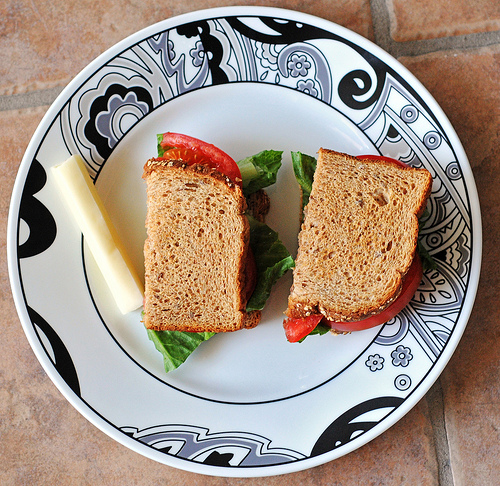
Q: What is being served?
A: Sandwiches for lunch.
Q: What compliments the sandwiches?
A: Mozzarella string cheese.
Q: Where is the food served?
A: On a white plate with blue border design.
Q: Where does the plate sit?
A: On a wooden table.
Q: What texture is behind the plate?
A: Tiles.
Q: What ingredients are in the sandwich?
A: Tomato and lettuce.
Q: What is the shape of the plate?
A: Round.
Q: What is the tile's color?
A: Terra cotta.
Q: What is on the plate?
A: A sandwich.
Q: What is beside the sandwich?
A: Cheese.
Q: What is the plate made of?
A: Ceramic.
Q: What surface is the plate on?
A: Tile.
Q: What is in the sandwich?
A: Lettuce.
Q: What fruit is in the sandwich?
A: Tomato.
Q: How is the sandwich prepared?
A: Halved.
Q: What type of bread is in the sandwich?
A: Whole wheat.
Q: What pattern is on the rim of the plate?
A: Abstract.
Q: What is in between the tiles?
A: Grout.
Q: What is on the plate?
A: A sandwich and cheese.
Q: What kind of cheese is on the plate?
A: White cheese.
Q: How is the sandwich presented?
A: Cut in half.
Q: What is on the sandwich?
A: Tomatoes and lettuce.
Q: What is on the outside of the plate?
A: A design.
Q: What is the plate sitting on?
A: Tile countertop or floor.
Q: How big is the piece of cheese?
A: Small.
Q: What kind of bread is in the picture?
A: Wheat bread.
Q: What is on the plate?
A: A sandwich.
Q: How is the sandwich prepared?
A: Halved.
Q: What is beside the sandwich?
A: Cheese.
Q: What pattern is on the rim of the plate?
A: Abstract.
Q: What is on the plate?
A: A sandwich is on the plate.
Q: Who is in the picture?
A: Nobody is in the picture.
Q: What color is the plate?
A: The plate is black,grey and white.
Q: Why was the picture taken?
A: To show how good the sandwich looks.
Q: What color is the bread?
A: The bread is brown.